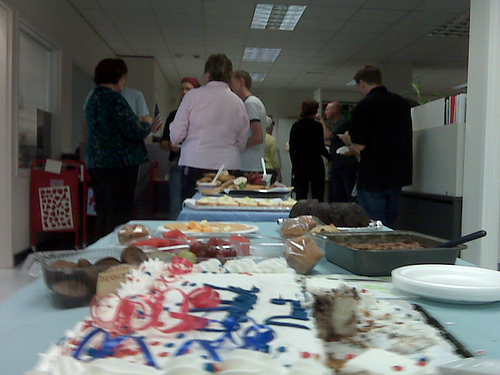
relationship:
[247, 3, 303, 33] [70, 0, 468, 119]
lights in ceiling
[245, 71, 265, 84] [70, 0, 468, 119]
lights in ceiling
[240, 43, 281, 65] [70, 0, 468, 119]
lights in ceiling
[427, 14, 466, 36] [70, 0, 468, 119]
lights in ceiling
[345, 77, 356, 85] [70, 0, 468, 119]
lights in ceiling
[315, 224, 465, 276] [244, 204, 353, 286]
pan on table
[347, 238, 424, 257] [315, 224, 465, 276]
food on pan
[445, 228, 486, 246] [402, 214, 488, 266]
handle of utensil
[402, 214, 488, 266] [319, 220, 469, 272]
utensil sticking out of platter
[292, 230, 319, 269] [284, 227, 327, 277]
muffin in bag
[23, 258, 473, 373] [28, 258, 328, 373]
cake with frosting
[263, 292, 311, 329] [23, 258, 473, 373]
writing on cake